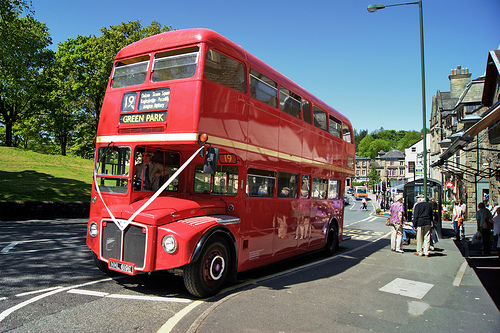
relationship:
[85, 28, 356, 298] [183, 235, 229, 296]
bus has wheel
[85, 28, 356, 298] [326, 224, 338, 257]
bus has wheel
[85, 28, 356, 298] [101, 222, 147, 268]
bus has grill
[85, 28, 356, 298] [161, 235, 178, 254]
bus has headlight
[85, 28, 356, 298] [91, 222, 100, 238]
bus has headlight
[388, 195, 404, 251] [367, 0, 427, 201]
person near light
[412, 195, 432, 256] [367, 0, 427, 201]
man near light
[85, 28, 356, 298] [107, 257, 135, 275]
bus has license plate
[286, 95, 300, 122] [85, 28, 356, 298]
man in bus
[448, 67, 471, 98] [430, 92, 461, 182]
chimney on building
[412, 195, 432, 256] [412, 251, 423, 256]
man with shoe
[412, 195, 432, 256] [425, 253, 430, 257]
man with shoe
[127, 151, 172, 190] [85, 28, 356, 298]
driver on bus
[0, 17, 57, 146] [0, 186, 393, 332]
tree beside road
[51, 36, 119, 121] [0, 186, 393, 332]
tree beside road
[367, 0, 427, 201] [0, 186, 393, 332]
light beside road